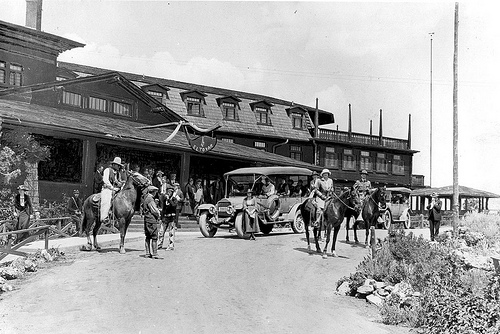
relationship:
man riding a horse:
[99, 148, 127, 228] [81, 167, 146, 252]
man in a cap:
[142, 183, 163, 259] [147, 183, 160, 192]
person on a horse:
[311, 169, 335, 227] [289, 180, 364, 257]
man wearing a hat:
[426, 192, 443, 241] [357, 162, 372, 177]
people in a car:
[253, 175, 311, 198] [198, 165, 326, 239]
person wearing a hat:
[238, 188, 262, 243] [245, 188, 252, 193]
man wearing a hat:
[99, 157, 125, 229] [107, 154, 128, 169]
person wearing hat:
[316, 161, 335, 205] [317, 164, 336, 178]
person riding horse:
[311, 169, 335, 227] [296, 185, 361, 259]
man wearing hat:
[99, 157, 125, 229] [112, 155, 123, 167]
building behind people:
[0, 16, 499, 236] [10, 151, 447, 259]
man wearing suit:
[428, 188, 444, 238] [430, 200, 441, 210]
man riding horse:
[99, 157, 125, 229] [78, 171, 155, 254]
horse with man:
[64, 148, 173, 263] [99, 157, 125, 229]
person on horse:
[354, 168, 396, 230] [330, 185, 392, 254]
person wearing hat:
[354, 169, 372, 222] [354, 166, 371, 176]